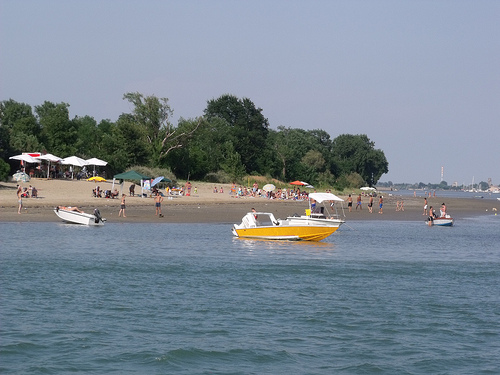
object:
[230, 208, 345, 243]
motor boat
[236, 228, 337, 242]
hull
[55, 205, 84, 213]
woman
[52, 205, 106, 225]
white boat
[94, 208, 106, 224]
black outboard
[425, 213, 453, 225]
motor boat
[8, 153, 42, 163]
umbrellas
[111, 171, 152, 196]
canopy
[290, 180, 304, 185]
umbrella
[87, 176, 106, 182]
umbrella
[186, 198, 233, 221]
sand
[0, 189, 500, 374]
water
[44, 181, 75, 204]
sand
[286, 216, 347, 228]
white boat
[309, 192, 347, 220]
sunshade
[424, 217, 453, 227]
boat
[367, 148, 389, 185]
trees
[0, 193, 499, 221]
beach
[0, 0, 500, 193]
sky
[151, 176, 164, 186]
umbrella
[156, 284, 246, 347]
waves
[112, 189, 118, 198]
people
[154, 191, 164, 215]
man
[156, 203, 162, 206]
blue trunks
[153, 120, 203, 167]
tree